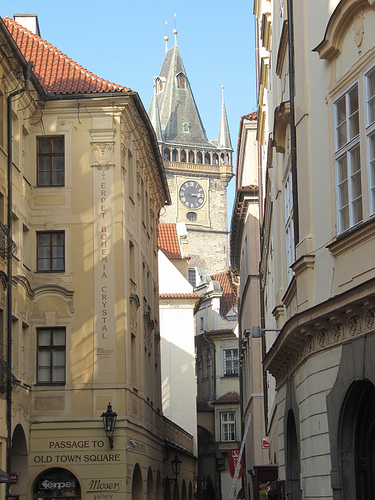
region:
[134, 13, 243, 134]
point roof of buildings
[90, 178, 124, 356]
text stone on side of building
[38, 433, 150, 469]
text saying " Passage to Old Town Square"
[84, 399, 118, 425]
black lamp post on building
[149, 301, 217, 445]
shadow overcasting on building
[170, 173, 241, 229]
black clock with roman numerals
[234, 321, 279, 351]
silver rounded building light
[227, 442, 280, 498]
red stoe front banner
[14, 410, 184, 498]
rounded arches of entry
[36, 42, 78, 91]
terracotta stone red roof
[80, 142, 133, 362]
this sign says erpet bohemia crystal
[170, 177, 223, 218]
the clock face is black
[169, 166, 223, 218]
the numbers are white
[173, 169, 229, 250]
the numbers are roman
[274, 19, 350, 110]
the building is cream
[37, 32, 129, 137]
the tiles are red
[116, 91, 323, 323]
the street is narrow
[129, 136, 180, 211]
archways on the clock tower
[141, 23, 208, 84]
two round balls on tower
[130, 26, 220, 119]
the roof tiles are slate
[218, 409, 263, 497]
a white ladder leaning against building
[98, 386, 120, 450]
a black lantern on side of building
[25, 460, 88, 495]
a rounded window with white writing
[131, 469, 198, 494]
seven arces over windows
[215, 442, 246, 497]
red and white flag on building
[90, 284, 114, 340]
letters that spell crystal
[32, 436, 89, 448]
black letters that say passage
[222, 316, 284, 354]
a gray light on building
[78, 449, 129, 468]
black letters that say square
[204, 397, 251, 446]
window on a building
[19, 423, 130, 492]
Directions to Old Town Square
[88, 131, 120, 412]
Advertisement for crystal store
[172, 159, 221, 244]
Clock on tall building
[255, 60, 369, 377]
White windows in tall building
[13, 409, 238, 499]
Shopping center on first floor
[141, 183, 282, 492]
Narrow alleyway between tall buildings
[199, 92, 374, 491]
Tall buildings in a city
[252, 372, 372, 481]
Archway of tall building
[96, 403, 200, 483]
Lamps for alley between buildings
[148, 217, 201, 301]
Red tile roofs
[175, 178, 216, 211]
black clock on church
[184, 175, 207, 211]
roman numerals on clock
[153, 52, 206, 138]
grey roof on church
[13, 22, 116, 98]
red roof on building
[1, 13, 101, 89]
red roof is pointed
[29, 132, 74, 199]
brown frame on window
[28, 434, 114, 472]
sign has brown letters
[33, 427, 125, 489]
brown letters on tan wall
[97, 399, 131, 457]
black lamp on tan building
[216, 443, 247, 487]
red and white sign